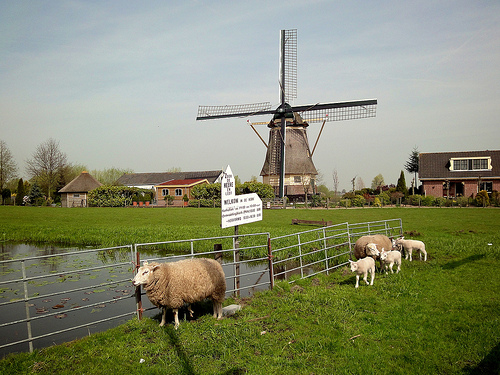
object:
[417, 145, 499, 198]
house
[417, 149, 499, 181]
roof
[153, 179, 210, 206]
building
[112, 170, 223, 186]
roof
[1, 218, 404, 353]
fence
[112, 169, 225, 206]
house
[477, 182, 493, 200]
window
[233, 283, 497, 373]
grass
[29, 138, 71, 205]
tree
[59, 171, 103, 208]
house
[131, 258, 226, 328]
laptop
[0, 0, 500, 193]
sky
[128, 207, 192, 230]
land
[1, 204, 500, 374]
grass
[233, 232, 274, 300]
guard rails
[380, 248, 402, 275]
baby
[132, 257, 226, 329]
adult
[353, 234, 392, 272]
adult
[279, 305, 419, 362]
grass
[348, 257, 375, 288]
animal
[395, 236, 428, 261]
animal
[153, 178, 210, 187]
roof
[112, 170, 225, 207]
building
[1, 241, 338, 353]
pond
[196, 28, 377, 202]
windmill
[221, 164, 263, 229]
sign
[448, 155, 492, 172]
window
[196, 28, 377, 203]
object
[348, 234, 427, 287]
group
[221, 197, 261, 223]
lettering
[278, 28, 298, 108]
arm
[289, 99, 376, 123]
arm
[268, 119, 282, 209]
arm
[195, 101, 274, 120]
arm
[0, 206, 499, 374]
ground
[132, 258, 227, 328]
animal